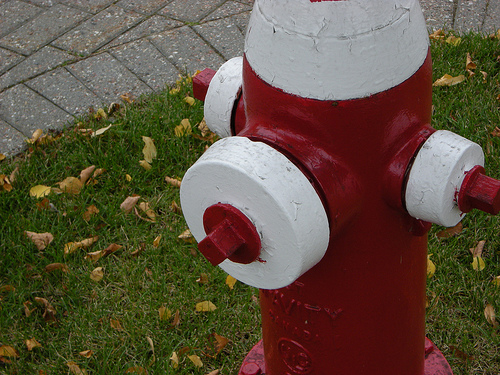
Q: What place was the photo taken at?
A: It was taken at the sidewalk.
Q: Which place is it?
A: It is a sidewalk.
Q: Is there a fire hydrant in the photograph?
A: Yes, there is a fire hydrant.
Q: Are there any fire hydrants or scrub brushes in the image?
A: Yes, there is a fire hydrant.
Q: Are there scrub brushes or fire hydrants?
A: Yes, there is a fire hydrant.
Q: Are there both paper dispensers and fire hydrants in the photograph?
A: No, there is a fire hydrant but no paper dispensers.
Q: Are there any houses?
A: No, there are no houses.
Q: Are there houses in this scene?
A: No, there are no houses.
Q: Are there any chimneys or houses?
A: No, there are no houses or chimneys.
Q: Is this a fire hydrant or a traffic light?
A: This is a fire hydrant.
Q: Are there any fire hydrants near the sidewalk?
A: Yes, there is a fire hydrant near the sidewalk.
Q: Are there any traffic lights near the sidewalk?
A: No, there is a fire hydrant near the sidewalk.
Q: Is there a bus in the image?
A: No, there are no buses.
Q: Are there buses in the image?
A: No, there are no buses.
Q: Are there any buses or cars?
A: No, there are no buses or cars.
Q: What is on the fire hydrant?
A: The sign is on the fire hydrant.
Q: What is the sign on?
A: The sign is on the hydrant.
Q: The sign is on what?
A: The sign is on the hydrant.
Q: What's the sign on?
A: The sign is on the hydrant.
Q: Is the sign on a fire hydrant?
A: Yes, the sign is on a fire hydrant.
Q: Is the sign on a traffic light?
A: No, the sign is on a fire hydrant.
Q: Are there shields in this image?
A: No, there are no shields.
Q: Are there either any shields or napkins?
A: No, there are no shields or napkins.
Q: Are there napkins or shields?
A: No, there are no shields or napkins.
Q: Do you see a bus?
A: No, there are no buses.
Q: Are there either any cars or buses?
A: No, there are no buses or cars.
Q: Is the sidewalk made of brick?
A: Yes, the sidewalk is made of brick.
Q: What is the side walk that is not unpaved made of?
A: The side walk is made of brick.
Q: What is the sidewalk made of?
A: The side walk is made of brick.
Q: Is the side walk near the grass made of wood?
A: No, the sidewalk is made of brick.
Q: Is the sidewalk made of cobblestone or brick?
A: The sidewalk is made of brick.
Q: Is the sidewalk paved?
A: Yes, the sidewalk is paved.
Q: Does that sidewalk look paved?
A: Yes, the sidewalk is paved.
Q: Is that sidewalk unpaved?
A: No, the sidewalk is paved.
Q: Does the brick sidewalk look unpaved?
A: No, the sidewalk is paved.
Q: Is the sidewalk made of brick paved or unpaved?
A: The side walk is paved.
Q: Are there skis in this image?
A: No, there are no skis.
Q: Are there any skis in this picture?
A: No, there are no skis.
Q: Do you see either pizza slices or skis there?
A: No, there are no skis or pizza slices.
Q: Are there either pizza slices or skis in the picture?
A: No, there are no skis or pizza slices.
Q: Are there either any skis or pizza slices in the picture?
A: No, there are no skis or pizza slices.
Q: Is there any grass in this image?
A: Yes, there is grass.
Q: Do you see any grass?
A: Yes, there is grass.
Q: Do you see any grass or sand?
A: Yes, there is grass.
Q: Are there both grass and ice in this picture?
A: No, there is grass but no ice.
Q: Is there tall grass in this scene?
A: Yes, there is tall grass.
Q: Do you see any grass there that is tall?
A: Yes, there is grass that is tall.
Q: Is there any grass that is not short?
A: Yes, there is tall grass.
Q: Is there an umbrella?
A: No, there are no umbrellas.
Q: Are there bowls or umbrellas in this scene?
A: No, there are no umbrellas or bowls.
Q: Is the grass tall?
A: Yes, the grass is tall.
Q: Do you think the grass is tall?
A: Yes, the grass is tall.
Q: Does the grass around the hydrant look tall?
A: Yes, the grass is tall.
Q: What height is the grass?
A: The grass is tall.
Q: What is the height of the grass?
A: The grass is tall.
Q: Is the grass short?
A: No, the grass is tall.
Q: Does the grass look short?
A: No, the grass is tall.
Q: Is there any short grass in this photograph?
A: No, there is grass but it is tall.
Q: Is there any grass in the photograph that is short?
A: No, there is grass but it is tall.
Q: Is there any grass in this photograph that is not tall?
A: No, there is grass but it is tall.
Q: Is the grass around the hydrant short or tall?
A: The grass is tall.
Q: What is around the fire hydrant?
A: The grass is around the fire hydrant.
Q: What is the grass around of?
A: The grass is around the hydrant.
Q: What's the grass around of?
A: The grass is around the hydrant.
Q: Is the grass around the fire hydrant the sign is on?
A: Yes, the grass is around the fire hydrant.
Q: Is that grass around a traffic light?
A: No, the grass is around the fire hydrant.